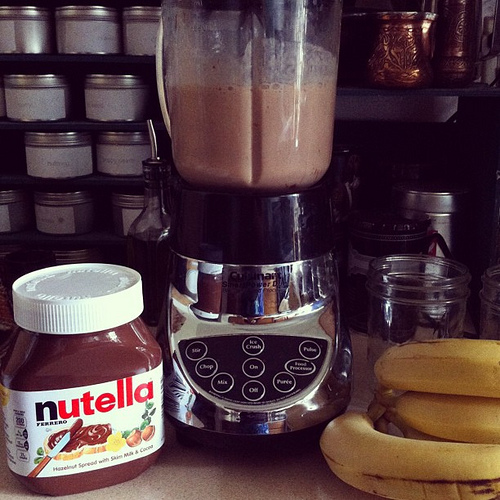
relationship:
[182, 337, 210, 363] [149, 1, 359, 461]
button on blender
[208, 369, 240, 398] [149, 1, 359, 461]
button on blender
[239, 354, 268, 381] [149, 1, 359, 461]
button on blender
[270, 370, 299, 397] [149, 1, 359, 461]
button on blender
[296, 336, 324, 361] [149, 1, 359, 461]
button on blender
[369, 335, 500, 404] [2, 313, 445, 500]
banana on counter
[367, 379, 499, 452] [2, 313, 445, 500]
banana on counter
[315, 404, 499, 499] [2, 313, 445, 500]
banana on counter